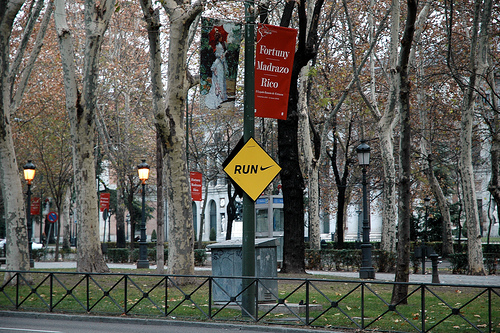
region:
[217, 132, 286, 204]
Street sign that says "run" with Nike symbol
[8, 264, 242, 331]
Fence next to street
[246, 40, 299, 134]
Red street sign with white lettering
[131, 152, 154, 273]
Street lamp inside park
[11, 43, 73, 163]
Leaves are changing colors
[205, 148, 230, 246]
Building located behind park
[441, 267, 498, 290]
Sidewalk inside park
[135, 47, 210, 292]
Tall tree standing inside park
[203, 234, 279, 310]
Utility box located inside park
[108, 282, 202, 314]
Grass behind fence has some leaves on it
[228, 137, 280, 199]
The yellow street sign with black writing.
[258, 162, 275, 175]
The Nike sign on the yellow and black sign.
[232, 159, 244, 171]
The letter R on the yellow and black sign.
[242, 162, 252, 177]
The letter U on the yellow and black sign.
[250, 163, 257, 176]
The letter N on the yellow and black sign.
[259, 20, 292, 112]
The red banner on the pole with white lettering on it.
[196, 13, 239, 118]
The picture on the banner to the left of the red banner on the pole.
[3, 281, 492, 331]
The black wrought iron gate.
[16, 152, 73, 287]
The lit lamp post on the left.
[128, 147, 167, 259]
The lit lamp post on the right.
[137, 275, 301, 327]
Short black gate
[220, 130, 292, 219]
Yellow and black advertisement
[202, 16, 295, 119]
Red and white signs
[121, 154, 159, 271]
Outdoor black lighting post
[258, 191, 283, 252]
Silver phone booth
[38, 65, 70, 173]
Brown and green leaves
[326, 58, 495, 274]
Tall white and brown trees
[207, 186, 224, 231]
White Greek-style building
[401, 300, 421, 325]
Grassy area with fallen leaves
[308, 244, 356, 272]
Short green bushes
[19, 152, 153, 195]
two street lights are on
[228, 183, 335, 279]
telephone booth next to sidewalk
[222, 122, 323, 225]
yellow and black street sign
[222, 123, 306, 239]
RUN written on the street sign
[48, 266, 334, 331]
fence is along the road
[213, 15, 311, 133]
banners hanging from the pole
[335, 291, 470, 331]
leaves in the grass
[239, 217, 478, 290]
sideway along grass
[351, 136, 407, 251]
street light is off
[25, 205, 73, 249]
round street sign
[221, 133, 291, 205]
yellow sign on black pole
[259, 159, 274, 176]
company logo on sign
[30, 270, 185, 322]
black guard railing beside path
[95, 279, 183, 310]
green grass growing behind guard rail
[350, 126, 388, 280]
black metal street light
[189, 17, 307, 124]
flags hanging from metal street pole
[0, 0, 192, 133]
row of trees covered in brown leaves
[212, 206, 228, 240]
statue on side of large building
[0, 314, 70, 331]
white striped painted on road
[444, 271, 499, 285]
grey concrete park path